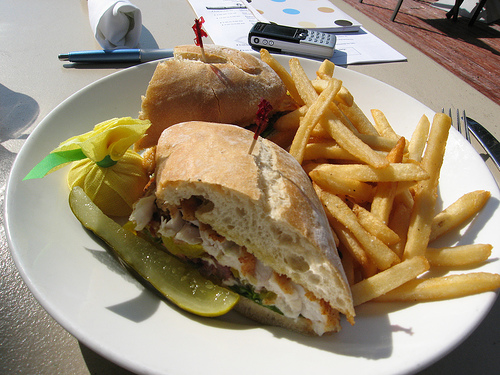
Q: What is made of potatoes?
A: French fries.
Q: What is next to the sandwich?
A: Pickle.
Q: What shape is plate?
A: Round.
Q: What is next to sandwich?
A: Fries.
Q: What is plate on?
A: Glass table.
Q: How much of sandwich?
A: Half.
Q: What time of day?
A: Bright afternoon.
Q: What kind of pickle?
A: Dill.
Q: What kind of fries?
A: French.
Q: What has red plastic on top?
A: The toothpicks.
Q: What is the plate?
A: Of food.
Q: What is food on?
A: Plate.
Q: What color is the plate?
A: White.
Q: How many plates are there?
A: One.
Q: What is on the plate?
A: Fries, sandwich and pickle.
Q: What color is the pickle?
A: Green.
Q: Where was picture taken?
A: Close to food.